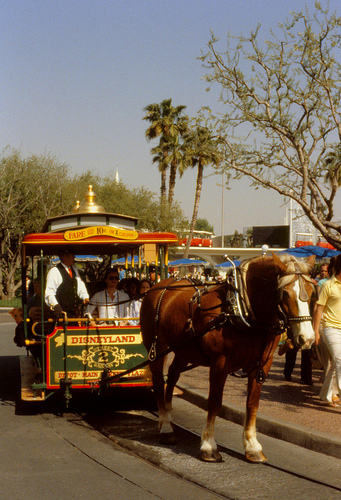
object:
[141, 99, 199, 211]
palm tree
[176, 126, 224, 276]
palm tree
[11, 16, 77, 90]
clouds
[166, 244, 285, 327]
wooden table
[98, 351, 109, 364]
number 2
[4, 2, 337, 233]
sky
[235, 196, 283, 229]
clouds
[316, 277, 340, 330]
shirt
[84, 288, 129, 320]
shirt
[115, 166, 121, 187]
tower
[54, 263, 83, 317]
coat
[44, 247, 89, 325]
man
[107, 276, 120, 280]
glasses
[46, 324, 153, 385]
sign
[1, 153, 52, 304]
tree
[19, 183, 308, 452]
carriage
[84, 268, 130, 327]
man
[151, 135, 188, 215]
tree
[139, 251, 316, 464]
horse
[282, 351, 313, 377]
pants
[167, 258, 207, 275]
umbrella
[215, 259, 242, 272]
umbrellas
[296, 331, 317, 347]
nose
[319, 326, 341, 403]
pants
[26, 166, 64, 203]
leaves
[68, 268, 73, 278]
tie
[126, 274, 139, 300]
people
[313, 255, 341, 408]
people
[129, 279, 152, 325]
people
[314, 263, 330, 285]
man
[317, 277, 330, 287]
shirt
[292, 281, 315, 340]
stripe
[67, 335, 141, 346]
disneyland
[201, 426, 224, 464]
hooves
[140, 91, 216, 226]
group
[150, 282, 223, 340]
fur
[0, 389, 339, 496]
street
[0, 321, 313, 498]
road